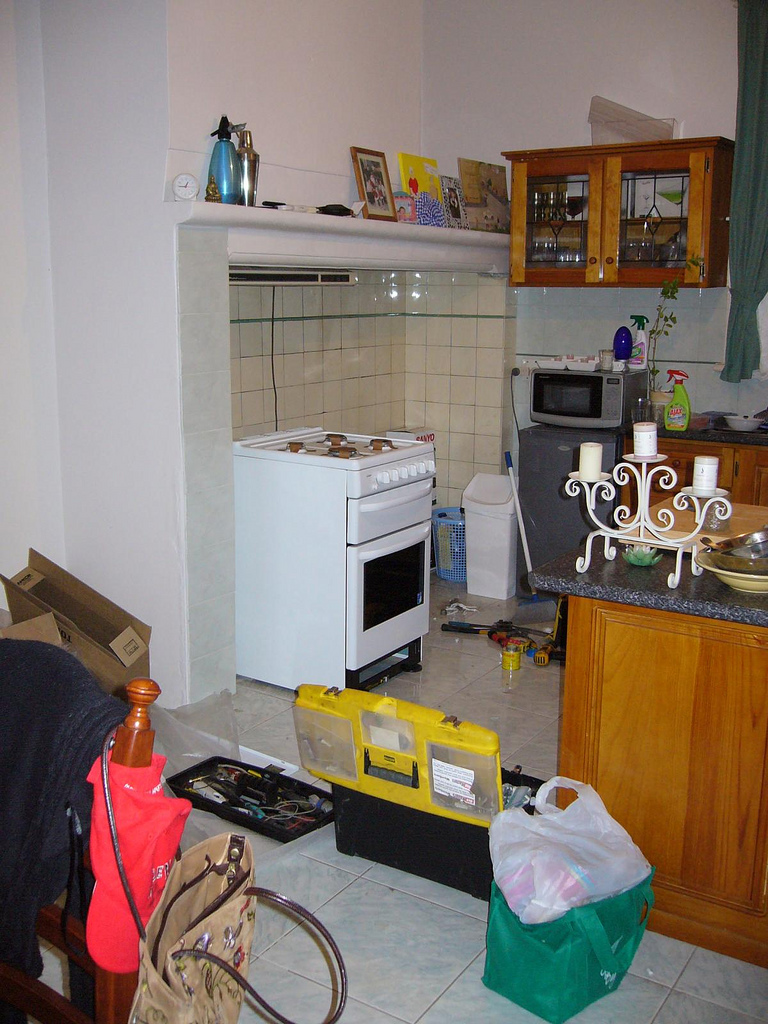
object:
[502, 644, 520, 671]
jar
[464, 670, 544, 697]
ground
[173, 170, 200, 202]
clock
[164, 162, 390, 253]
shelf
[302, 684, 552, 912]
tool box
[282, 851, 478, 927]
ground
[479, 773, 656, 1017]
bag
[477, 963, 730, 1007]
ground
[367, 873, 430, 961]
ground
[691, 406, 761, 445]
counter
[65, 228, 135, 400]
wall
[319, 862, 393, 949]
floor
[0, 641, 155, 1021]
chair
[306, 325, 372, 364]
tile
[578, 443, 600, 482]
candle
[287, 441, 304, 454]
burner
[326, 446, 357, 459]
burner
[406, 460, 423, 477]
knob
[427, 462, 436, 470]
knob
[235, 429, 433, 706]
stove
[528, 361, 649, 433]
microwave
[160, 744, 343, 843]
toptray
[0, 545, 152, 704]
box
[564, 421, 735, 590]
candle holder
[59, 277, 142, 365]
tile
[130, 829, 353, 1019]
bag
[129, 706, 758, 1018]
floor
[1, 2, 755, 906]
kitchen